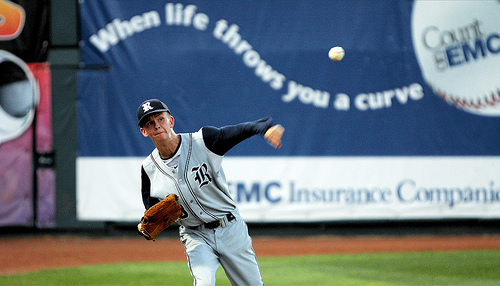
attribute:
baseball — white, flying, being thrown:
[327, 44, 342, 59]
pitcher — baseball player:
[135, 99, 284, 285]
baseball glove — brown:
[139, 194, 186, 234]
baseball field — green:
[2, 223, 499, 285]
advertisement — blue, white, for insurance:
[77, 0, 499, 222]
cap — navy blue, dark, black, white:
[135, 99, 165, 120]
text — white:
[86, 2, 424, 108]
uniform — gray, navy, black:
[139, 117, 279, 285]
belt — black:
[183, 213, 235, 230]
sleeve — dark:
[200, 117, 276, 156]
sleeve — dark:
[141, 168, 163, 210]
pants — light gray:
[179, 210, 265, 285]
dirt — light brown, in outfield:
[0, 233, 498, 274]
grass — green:
[1, 249, 499, 284]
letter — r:
[190, 165, 213, 185]